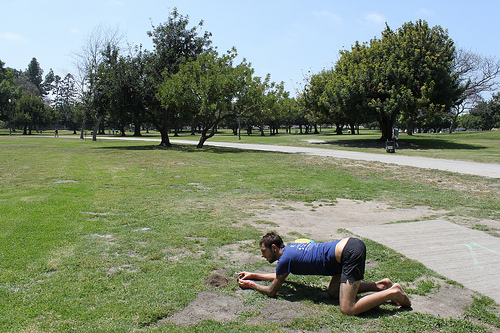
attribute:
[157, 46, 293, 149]
tree — gree, green, lush green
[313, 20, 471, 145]
tree — gree, green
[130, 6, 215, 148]
tree — green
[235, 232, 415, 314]
man — crawling, kneeling, shoeless, pulling, light skinned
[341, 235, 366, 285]
shorts — blue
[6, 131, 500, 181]
pathway — concrete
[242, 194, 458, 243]
spot — bare, dirt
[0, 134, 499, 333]
grass — green, area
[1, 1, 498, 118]
sky — blue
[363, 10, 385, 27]
cloud — white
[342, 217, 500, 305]
walkway — wood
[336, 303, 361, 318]
knee — bent